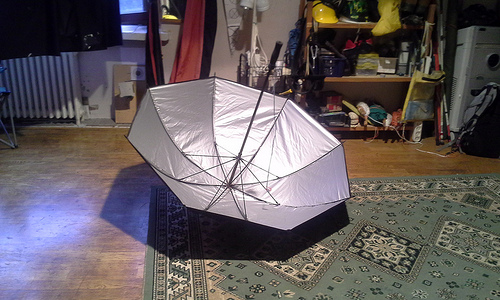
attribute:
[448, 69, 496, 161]
backpack — black, white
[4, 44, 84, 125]
radiator — white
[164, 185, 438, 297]
rug — green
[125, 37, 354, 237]
umbrella — open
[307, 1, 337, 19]
safety helmet — yellow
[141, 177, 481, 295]
area rug — green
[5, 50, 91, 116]
wall furnace — white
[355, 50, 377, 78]
boxes — plastic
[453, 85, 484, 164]
backpack — gray, black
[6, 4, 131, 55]
curtain — black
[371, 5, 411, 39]
shopping bag — yellow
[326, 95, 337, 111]
box — cardboard, brown, red